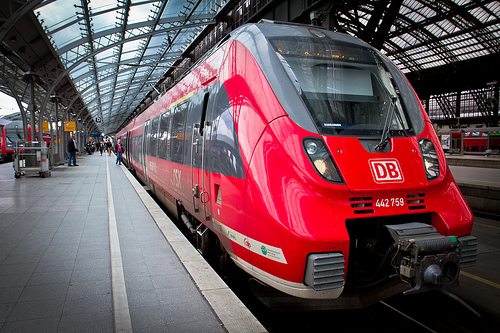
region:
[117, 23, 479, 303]
train is not moving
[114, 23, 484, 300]
train is at train station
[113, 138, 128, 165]
person is next to the train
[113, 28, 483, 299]
train number is 442759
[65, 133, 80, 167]
person is looking at train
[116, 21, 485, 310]
train is a passenger train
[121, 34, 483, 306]
train is red and gray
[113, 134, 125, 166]
person has red shirt on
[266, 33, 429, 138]
window is clean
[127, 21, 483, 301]
train lights are not turned on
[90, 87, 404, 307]
a train on thet rack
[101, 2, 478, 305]
a train on the train track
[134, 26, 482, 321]
a train at the station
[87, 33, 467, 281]
a train at a train station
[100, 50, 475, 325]
a red train on tracks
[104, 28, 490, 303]
a red train on train tracks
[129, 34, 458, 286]
a passenger train on the tracks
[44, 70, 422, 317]
a passenger train on train tracks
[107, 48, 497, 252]
a red passenger train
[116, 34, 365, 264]
a red passenger train on tracks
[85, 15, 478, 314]
a red, grey, and white electric train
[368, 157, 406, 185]
db in white letters on a train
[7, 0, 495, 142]
glass sun roof of train station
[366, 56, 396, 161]
wind shield wiper on front of train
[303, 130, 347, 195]
left head light of train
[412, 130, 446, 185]
right head light of train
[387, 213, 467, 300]
electric motor on front of train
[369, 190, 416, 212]
white numbers 442759 on train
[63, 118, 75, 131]
yellow sign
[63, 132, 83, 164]
person standing on train platform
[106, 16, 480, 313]
train is red and black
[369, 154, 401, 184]
red letters on train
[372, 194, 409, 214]
white numbers on train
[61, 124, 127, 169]
people walking on platform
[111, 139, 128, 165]
persons' shirt is red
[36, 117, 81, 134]
yellow signs in train station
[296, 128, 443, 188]
lights on front of train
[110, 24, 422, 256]
reflection on the train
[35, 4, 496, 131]
glass windows on ceiling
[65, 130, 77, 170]
person's shirt is black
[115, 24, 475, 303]
red and grey train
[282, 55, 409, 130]
wind shield on train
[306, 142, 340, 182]
head light on train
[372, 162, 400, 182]
white decal on train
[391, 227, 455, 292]
black connector on train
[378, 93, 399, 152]
wind shield wiper on train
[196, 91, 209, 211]
door on train car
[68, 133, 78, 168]
person wearing denim jeans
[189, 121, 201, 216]
metal handle on door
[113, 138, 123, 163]
person wearing red shirt